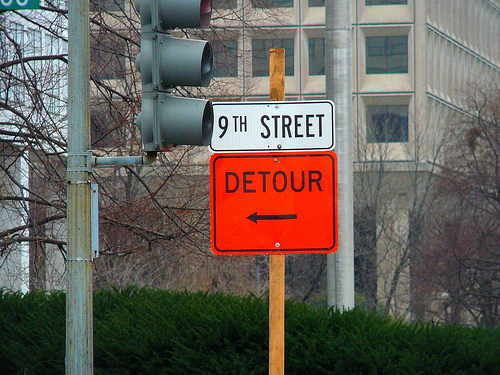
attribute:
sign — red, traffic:
[189, 152, 339, 254]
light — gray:
[68, 137, 131, 290]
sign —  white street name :
[159, 91, 406, 182]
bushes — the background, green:
[0, 287, 500, 373]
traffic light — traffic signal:
[135, 3, 223, 154]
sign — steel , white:
[189, 129, 360, 266]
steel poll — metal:
[53, 7, 105, 370]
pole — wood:
[267, 47, 284, 374]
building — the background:
[197, 10, 496, 288]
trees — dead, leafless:
[355, 89, 495, 331]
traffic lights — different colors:
[121, 1, 226, 161]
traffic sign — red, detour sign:
[211, 155, 339, 259]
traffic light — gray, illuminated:
[129, 0, 214, 162]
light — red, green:
[131, 3, 216, 153]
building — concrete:
[366, 39, 417, 94]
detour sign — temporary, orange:
[188, 144, 343, 249]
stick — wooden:
[267, 46, 286, 371]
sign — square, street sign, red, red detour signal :
[204, 151, 342, 255]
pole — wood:
[264, 40, 301, 375]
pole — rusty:
[54, 1, 97, 371]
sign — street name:
[205, 92, 340, 268]